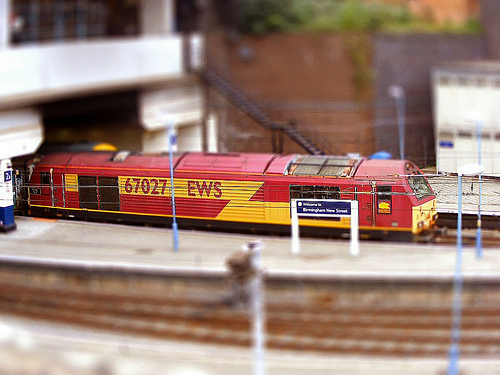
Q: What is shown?
A: Toy trains.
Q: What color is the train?
A: Red.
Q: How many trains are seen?
A: One.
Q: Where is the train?
A: On the tracks.